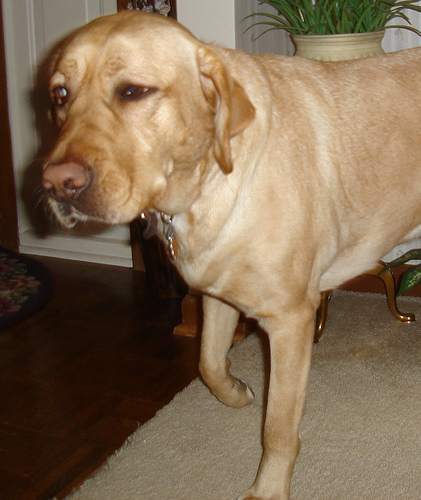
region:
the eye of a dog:
[108, 77, 162, 107]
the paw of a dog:
[197, 355, 260, 416]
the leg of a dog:
[184, 283, 259, 420]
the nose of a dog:
[40, 156, 100, 205]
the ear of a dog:
[197, 41, 258, 185]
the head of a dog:
[20, 5, 250, 249]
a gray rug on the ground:
[61, 286, 419, 499]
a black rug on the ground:
[0, 239, 59, 331]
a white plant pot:
[283, 26, 391, 68]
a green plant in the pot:
[235, 0, 419, 57]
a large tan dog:
[3, 2, 372, 356]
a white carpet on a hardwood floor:
[58, 284, 366, 489]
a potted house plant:
[242, 0, 420, 67]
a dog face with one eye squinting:
[31, 13, 222, 234]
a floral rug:
[0, 242, 57, 321]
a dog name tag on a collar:
[138, 197, 192, 265]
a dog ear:
[189, 41, 259, 178]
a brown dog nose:
[34, 127, 152, 235]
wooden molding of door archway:
[147, 275, 255, 355]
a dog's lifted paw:
[180, 292, 260, 420]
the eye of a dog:
[119, 78, 149, 115]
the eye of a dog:
[47, 75, 74, 106]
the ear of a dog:
[201, 60, 258, 166]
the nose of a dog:
[39, 159, 91, 193]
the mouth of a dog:
[52, 193, 111, 231]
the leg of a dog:
[241, 300, 310, 497]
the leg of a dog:
[199, 295, 260, 411]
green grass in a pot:
[258, 0, 407, 28]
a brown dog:
[35, 6, 412, 499]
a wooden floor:
[0, 251, 197, 497]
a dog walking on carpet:
[20, 37, 419, 456]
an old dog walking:
[7, 4, 378, 352]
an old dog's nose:
[20, 149, 102, 219]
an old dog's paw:
[197, 357, 258, 407]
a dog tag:
[140, 208, 206, 271]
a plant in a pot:
[248, 6, 406, 62]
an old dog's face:
[10, 6, 288, 251]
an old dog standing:
[14, 18, 410, 422]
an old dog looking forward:
[19, 12, 267, 265]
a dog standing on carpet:
[25, 21, 352, 354]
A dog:
[26, 10, 419, 376]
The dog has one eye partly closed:
[37, 50, 171, 123]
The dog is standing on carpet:
[184, 342, 331, 492]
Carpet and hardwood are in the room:
[26, 292, 218, 473]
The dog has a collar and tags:
[119, 163, 221, 263]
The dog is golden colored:
[26, 3, 418, 253]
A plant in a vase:
[247, 2, 414, 77]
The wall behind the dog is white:
[8, 6, 236, 261]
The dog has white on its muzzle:
[28, 143, 174, 233]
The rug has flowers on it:
[2, 245, 71, 347]